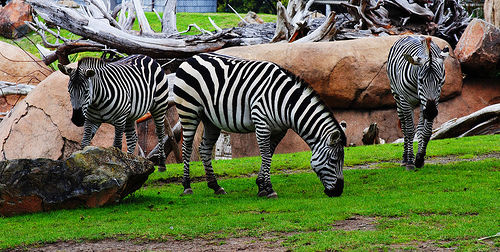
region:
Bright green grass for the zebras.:
[373, 173, 487, 235]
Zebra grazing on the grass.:
[302, 121, 357, 201]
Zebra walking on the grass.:
[381, 28, 454, 174]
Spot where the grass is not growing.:
[332, 210, 384, 241]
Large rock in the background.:
[278, 34, 384, 108]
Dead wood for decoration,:
[36, 16, 267, 48]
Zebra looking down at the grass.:
[45, 52, 170, 131]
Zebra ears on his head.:
[380, 42, 456, 73]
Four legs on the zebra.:
[151, 127, 294, 201]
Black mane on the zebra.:
[285, 73, 340, 137]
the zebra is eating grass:
[278, 112, 379, 230]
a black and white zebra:
[66, 54, 171, 131]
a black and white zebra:
[155, 16, 379, 250]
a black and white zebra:
[371, 22, 446, 199]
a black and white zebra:
[29, 25, 178, 159]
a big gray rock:
[0, 141, 173, 212]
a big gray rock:
[8, 136, 125, 189]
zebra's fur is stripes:
[38, 40, 211, 184]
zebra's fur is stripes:
[154, 20, 343, 249]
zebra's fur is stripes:
[369, 20, 451, 181]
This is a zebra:
[55, 35, 180, 181]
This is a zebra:
[176, 25, 381, 237]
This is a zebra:
[359, 33, 464, 183]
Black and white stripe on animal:
[262, 58, 284, 96]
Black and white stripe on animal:
[222, 54, 263, 96]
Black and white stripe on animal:
[175, 56, 215, 86]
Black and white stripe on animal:
[170, 94, 225, 139]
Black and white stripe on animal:
[211, 109, 305, 146]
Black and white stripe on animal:
[389, 40, 449, 104]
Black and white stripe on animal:
[68, 62, 117, 103]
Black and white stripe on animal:
[110, 61, 162, 103]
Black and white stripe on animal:
[106, 98, 161, 143]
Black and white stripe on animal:
[255, 163, 300, 193]